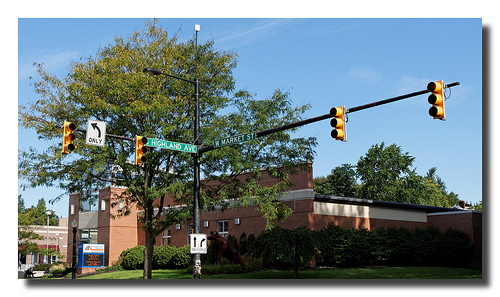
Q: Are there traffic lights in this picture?
A: Yes, there is a traffic light.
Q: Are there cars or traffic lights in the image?
A: Yes, there is a traffic light.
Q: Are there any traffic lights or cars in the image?
A: Yes, there is a traffic light.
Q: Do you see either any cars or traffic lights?
A: Yes, there is a traffic light.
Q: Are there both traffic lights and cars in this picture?
A: No, there is a traffic light but no cars.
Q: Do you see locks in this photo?
A: No, there are no locks.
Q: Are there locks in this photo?
A: No, there are no locks.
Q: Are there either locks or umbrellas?
A: No, there are no locks or umbrellas.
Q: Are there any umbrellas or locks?
A: No, there are no locks or umbrellas.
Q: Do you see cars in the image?
A: No, there are no cars.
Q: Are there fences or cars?
A: No, there are no cars or fences.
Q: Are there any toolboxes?
A: No, there are no toolboxes.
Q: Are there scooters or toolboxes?
A: No, there are no toolboxes or scooters.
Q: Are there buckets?
A: No, there are no buckets.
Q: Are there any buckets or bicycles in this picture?
A: No, there are no buckets or bicycles.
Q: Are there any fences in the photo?
A: No, there are no fences.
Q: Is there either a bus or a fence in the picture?
A: No, there are no fences or buses.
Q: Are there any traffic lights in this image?
A: Yes, there is a traffic light.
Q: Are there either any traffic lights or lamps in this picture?
A: Yes, there is a traffic light.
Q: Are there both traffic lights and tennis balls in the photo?
A: No, there is a traffic light but no tennis balls.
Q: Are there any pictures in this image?
A: No, there are no pictures.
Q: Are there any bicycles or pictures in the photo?
A: No, there are no pictures or bicycles.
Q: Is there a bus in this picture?
A: No, there are no buses.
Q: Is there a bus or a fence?
A: No, there are no buses or fences.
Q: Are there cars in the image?
A: No, there are no cars.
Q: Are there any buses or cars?
A: No, there are no cars or buses.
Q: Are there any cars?
A: No, there are no cars.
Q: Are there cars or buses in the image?
A: No, there are no cars or buses.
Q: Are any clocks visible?
A: No, there are no clocks.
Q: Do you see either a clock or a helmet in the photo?
A: No, there are no clocks or helmets.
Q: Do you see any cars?
A: No, there are no cars.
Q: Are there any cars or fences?
A: No, there are no cars or fences.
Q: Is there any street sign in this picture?
A: Yes, there is a street sign.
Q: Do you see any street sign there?
A: Yes, there is a street sign.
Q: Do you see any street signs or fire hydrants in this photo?
A: Yes, there is a street sign.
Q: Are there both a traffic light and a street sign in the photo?
A: Yes, there are both a street sign and a traffic light.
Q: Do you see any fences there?
A: No, there are no fences.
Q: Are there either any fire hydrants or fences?
A: No, there are no fences or fire hydrants.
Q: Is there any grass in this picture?
A: Yes, there is grass.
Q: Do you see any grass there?
A: Yes, there is grass.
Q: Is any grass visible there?
A: Yes, there is grass.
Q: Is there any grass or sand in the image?
A: Yes, there is grass.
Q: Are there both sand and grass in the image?
A: No, there is grass but no sand.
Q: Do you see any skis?
A: No, there are no skis.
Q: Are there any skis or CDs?
A: No, there are no skis or cds.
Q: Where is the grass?
A: The grass is on the ground.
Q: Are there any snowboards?
A: No, there are no snowboards.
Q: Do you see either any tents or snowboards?
A: No, there are no snowboards or tents.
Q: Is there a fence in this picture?
A: No, there are no fences.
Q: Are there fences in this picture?
A: No, there are no fences.